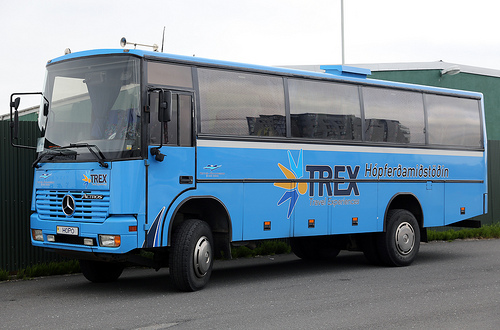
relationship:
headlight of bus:
[98, 231, 118, 247] [8, 29, 488, 291]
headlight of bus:
[32, 228, 43, 241] [8, 29, 488, 291]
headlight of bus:
[29, 227, 51, 244] [42, 37, 487, 262]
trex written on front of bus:
[306, 166, 360, 196] [8, 29, 488, 291]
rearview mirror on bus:
[156, 85, 173, 160] [8, 29, 488, 291]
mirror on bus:
[4, 82, 36, 158] [8, 29, 488, 291]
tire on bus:
[380, 189, 428, 274] [8, 29, 488, 291]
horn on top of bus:
[112, 39, 163, 49] [8, 29, 488, 291]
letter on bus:
[306, 165, 362, 196] [366, 103, 466, 163]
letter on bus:
[306, 165, 362, 196] [8, 29, 488, 291]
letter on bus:
[334, 165, 349, 196] [8, 29, 488, 291]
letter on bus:
[364, 162, 449, 179] [25, 45, 488, 289]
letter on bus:
[364, 162, 449, 179] [26, 37, 352, 267]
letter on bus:
[364, 162, 449, 179] [8, 29, 488, 291]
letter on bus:
[393, 160, 403, 181] [25, 45, 488, 289]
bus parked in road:
[8, 29, 488, 291] [0, 237, 498, 328]